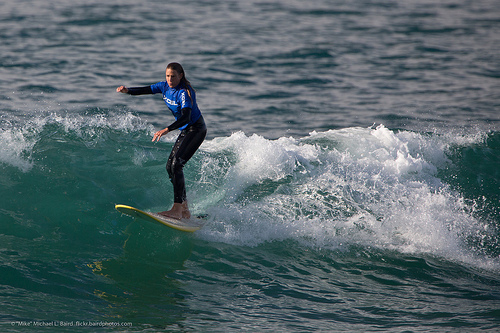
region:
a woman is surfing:
[77, 34, 267, 301]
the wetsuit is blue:
[71, 28, 279, 291]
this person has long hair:
[99, 33, 258, 268]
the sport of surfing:
[94, 33, 259, 235]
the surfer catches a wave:
[79, 37, 301, 310]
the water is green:
[88, 4, 285, 294]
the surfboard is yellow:
[81, 31, 285, 326]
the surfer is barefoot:
[82, 34, 241, 269]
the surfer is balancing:
[91, 16, 268, 268]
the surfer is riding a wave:
[89, 34, 494, 331]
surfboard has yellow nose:
[114, 201, 146, 218]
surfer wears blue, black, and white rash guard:
[132, 80, 204, 128]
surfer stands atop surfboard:
[106, 58, 216, 237]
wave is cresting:
[3, 108, 110, 248]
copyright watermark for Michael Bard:
[10, 318, 135, 328]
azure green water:
[11, 186, 79, 311]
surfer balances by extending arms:
[112, 58, 208, 146]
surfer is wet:
[113, 57, 209, 219]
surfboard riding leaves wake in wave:
[108, 162, 380, 247]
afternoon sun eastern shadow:
[161, 59, 184, 92]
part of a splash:
[262, 182, 315, 255]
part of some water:
[251, 287, 289, 325]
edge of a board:
[112, 193, 143, 221]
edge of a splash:
[261, 215, 328, 267]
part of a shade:
[163, 304, 185, 322]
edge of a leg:
[165, 207, 180, 219]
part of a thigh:
[173, 130, 200, 161]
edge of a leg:
[176, 177, 191, 199]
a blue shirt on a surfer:
[146, 78, 199, 131]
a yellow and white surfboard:
[111, 196, 200, 239]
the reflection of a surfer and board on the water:
[86, 225, 190, 325]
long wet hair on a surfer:
[168, 61, 198, 100]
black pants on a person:
[161, 109, 210, 206]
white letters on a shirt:
[160, 94, 182, 110]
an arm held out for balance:
[113, 79, 164, 101]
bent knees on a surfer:
[150, 143, 195, 185]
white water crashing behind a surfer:
[217, 128, 382, 243]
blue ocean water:
[3, 0, 496, 93]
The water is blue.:
[267, 13, 435, 100]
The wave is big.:
[7, 78, 477, 268]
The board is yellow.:
[110, 193, 257, 259]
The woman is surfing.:
[83, 35, 255, 261]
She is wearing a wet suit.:
[95, 51, 237, 258]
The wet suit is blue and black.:
[109, 67, 237, 258]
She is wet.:
[87, 55, 245, 330]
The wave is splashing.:
[33, 126, 475, 301]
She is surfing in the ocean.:
[74, 4, 479, 304]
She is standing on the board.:
[59, 51, 246, 234]